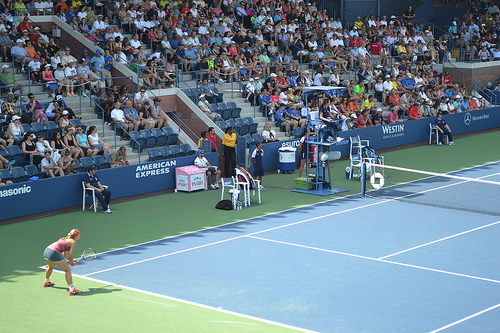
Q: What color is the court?
A: Blue and white.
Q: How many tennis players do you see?
A: 1.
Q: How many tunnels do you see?
A: 2.